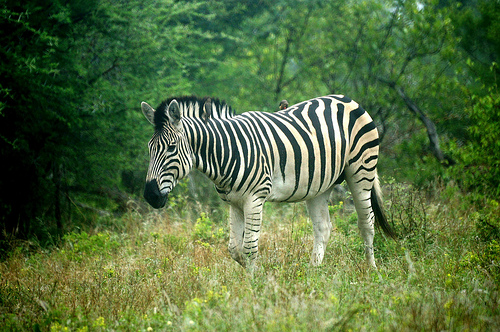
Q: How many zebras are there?
A: One.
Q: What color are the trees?
A: Green.